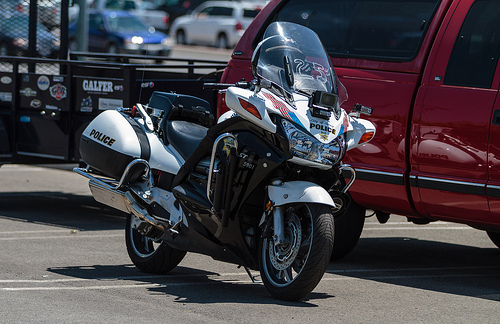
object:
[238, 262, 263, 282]
kickstand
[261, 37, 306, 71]
helmet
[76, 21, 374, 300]
bike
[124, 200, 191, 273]
tire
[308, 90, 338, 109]
lights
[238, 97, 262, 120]
lights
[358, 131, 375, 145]
lights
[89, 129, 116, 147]
word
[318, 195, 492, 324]
ground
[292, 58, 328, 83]
25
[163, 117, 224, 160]
seat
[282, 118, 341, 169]
headlight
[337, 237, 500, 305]
shadow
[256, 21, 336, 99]
windshield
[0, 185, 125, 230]
shadow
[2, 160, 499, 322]
road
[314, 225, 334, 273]
tread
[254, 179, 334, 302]
front tire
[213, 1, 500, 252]
truck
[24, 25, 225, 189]
trailer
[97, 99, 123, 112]
sticker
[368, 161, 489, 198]
trim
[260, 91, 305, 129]
american flags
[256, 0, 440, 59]
window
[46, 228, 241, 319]
street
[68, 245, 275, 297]
shadow